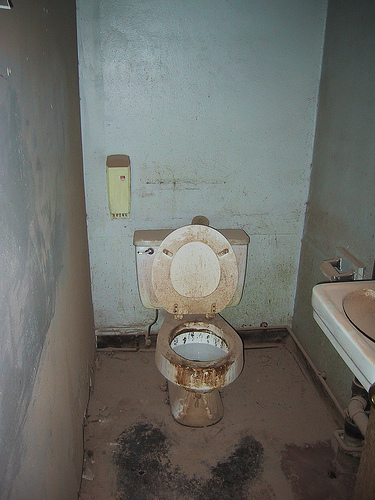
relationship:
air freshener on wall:
[103, 154, 133, 222] [74, 1, 327, 345]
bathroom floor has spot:
[81, 343, 357, 497] [113, 424, 265, 499]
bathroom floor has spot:
[81, 343, 357, 497] [113, 424, 265, 494]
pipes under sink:
[347, 393, 369, 446] [310, 274, 374, 389]